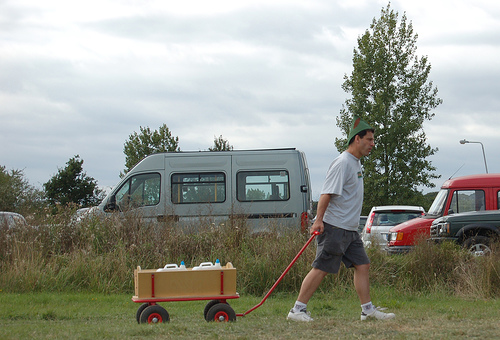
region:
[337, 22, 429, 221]
a green big tree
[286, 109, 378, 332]
a tall men walking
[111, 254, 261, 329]
a small vehicle taking by men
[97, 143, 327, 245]
a big truck backside of men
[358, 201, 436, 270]
back part of a car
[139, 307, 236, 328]
two wheels of a small vehicle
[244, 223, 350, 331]
a small stand to drag small vehicle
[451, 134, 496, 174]
the top portion of a electric bulb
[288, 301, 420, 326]
two shoes of a men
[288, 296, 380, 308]
two socks of a men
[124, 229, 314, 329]
Little red wagon being pulled.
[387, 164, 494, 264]
Red vehicle in the background.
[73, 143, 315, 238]
Gray van behind man.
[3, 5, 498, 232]
Clouds in the sky.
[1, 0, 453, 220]
Trees in the background.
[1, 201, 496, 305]
Tall grasses behind man.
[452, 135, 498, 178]
Street light in the background.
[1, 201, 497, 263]
Numerous vehicles parked in the background.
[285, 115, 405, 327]
Man pulling wagon.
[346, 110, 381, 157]
Man has green hat on.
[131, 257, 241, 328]
a wooden and red wagon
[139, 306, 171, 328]
a black and red wagon wheel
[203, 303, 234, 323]
a black and red wagon wheel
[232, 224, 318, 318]
a red metal wagon handle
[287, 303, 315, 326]
a white tennis shoe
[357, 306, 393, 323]
a white tennis shoe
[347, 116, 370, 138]
a red and green hat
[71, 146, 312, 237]
a grey van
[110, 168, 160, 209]
a grey van window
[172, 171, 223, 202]
a grey van window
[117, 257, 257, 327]
red wagon with brown box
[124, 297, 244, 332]
black tires with red centers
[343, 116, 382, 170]
man wears green baseball cap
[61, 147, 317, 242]
gray van facing left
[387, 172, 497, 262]
red van behind black car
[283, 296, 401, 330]
man's left foot in front of right foot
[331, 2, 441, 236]
tall green tree behind cars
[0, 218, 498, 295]
overgrown grass behind trimmed grass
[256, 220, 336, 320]
man pulls wagon with right hand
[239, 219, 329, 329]
red handle on red wagon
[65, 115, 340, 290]
a large grey van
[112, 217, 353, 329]
a wagon with a red handle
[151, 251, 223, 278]
a couple plastic containers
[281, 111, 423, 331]
a man dressed in grey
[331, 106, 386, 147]
a pointed green hat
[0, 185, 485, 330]
a grassy area near the road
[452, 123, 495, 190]
a tall white street light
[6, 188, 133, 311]
a few overgrown plants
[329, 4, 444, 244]
a single tall tree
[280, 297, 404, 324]
a pair of white tennis shoes